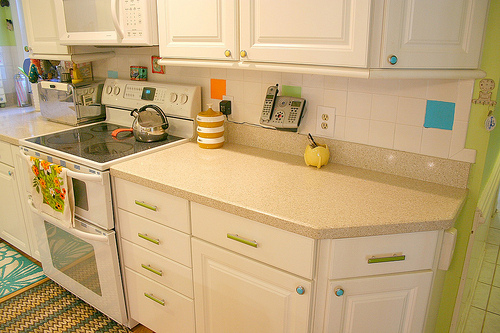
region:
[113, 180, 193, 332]
green handles on white drawers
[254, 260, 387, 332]
blue handles on white cupboard doors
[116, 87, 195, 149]
tea kettle on stove burner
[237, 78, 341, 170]
telephone on wall above counter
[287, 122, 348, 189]
yellow ceramic pen holder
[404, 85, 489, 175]
blue on white tile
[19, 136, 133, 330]
flowered kitchen towel on oven door handle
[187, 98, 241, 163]
striped container on countertop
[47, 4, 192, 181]
white microwave oven over stove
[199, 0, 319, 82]
yellow knob handles on cupboard doors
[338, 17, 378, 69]
part of a board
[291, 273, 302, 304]
part of a handle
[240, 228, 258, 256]
part of a handle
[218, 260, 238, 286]
edge fo a board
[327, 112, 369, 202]
;part of a wall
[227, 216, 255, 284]
part of a handle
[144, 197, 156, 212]
part of a handle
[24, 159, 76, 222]
Towell hanging from stove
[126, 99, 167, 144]
Kettle on the back burner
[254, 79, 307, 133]
Landline telephone on wall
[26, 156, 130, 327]
Double oven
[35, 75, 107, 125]
Silver bread box on the counter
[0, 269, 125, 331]
Striped rug in front of stove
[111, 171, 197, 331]
Cabinet with four pull-out drawers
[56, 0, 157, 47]
White microwave oven above stove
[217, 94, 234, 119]
Plug from phone in outlet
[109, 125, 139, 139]
Orange spoon rest next to kettle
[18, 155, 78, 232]
A green/yellow/orange towel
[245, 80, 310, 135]
A silver wall phone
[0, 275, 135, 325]
A yellow/blue rug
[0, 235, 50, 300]
A blue/white floor mat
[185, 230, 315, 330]
A white counter cabinet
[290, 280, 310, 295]
A blue cabinet handle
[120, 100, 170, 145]
A tea pot sitting on a burner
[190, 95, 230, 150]
A yellow/white dispenser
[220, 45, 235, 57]
A yellow cabinet handle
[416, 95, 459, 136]
A piece of blue paper on the wall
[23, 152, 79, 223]
dish cloth hanging from oven handle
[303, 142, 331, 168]
yellow vase on countertop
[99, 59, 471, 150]
white tiles on wall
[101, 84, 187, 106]
white knobs on stovetop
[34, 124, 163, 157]
black top of stove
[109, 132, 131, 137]
orange spoon rest on stovetop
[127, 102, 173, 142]
black and silver tea kettle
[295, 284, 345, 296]
blue knobs on white cabinets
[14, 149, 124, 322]
two doors to oven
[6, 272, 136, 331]
rug in front of oven